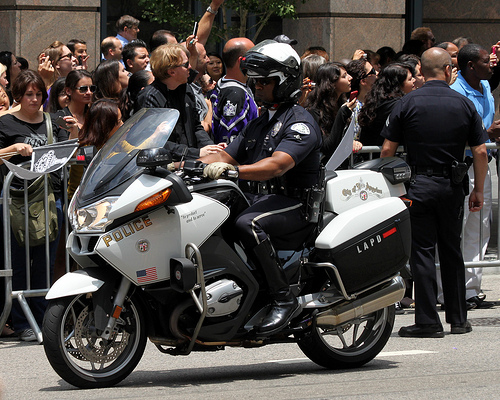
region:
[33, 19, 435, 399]
police officer on a motorcycle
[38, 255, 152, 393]
front tire of motorcycle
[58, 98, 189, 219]
windshielf of motorcycle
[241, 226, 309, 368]
black knee-high motorcycle boots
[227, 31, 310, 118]
black and white motorcycle helmet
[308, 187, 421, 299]
cargo box of motorcycle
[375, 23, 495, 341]
back of standing police officer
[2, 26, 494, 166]
crowd of people behind a fence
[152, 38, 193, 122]
man with blonde hair wearing sunglasses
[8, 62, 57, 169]
woman wearing black hair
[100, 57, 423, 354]
Cop in a Bike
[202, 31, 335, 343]
police office riding motorcycle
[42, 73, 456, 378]
white motorcycle with office on it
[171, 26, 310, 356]
office wearing black boots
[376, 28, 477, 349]
police office standing behind motorcycle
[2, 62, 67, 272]
woman wearing black shirt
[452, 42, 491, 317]
man wearing blue shirt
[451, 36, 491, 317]
man wearing white pants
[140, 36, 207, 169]
man wearing dark sunglasses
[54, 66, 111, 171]
woman wearing dark sunglasses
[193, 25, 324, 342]
police officer wearing beige gloves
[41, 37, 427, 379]
policeman sitting on motorcyle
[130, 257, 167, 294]
american flag on bike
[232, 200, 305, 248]
white stripe on pants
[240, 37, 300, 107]
helmet on policeman's head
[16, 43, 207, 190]
people on side of road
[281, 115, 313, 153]
patch on uniform sleeve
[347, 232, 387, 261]
white letters on black case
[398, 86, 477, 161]
black shirt on policeman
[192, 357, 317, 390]
shadow of bike on ground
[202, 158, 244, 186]
gloved hand on handlebar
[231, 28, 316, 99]
The man has a helmet on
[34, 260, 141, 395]
The front tire is small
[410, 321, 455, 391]
The pavement is gray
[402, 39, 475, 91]
The man is bald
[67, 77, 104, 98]
The woman has sun glasses on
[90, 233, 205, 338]
The bike has an american flag on it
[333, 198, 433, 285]
The bike says LAPD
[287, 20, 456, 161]
The people are looking away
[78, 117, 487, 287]
The bike is white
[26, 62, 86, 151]
The woman has a black shirt on